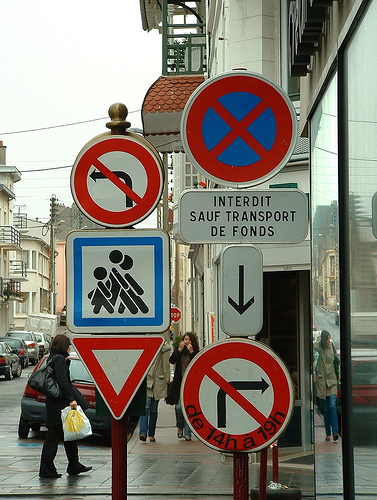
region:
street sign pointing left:
[47, 117, 168, 223]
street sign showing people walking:
[58, 223, 199, 339]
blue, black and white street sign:
[65, 228, 175, 330]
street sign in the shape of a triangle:
[68, 326, 169, 419]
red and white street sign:
[65, 332, 168, 423]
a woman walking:
[23, 334, 141, 485]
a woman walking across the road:
[14, 334, 178, 488]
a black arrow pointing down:
[213, 243, 269, 341]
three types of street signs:
[63, 126, 184, 417]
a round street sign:
[169, 63, 298, 190]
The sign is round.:
[173, 64, 300, 189]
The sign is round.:
[172, 334, 298, 454]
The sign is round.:
[67, 133, 167, 229]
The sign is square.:
[60, 225, 173, 334]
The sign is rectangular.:
[217, 243, 266, 337]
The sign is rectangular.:
[174, 187, 312, 246]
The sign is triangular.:
[67, 331, 173, 422]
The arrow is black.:
[223, 257, 258, 318]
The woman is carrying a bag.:
[20, 330, 97, 487]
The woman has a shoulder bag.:
[22, 333, 98, 488]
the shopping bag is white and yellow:
[60, 405, 97, 437]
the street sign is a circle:
[183, 349, 291, 455]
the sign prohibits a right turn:
[180, 337, 294, 454]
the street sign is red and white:
[72, 336, 167, 417]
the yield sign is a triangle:
[69, 334, 164, 420]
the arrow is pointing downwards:
[219, 245, 262, 336]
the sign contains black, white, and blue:
[68, 235, 161, 327]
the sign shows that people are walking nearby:
[72, 235, 160, 327]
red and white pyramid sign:
[69, 332, 158, 413]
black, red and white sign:
[178, 336, 290, 450]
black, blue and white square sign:
[72, 236, 159, 324]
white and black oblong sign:
[218, 242, 261, 332]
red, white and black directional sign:
[70, 130, 161, 225]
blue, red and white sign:
[178, 67, 296, 186]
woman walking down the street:
[163, 329, 196, 440]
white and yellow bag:
[59, 402, 90, 438]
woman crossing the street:
[36, 332, 88, 476]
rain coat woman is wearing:
[312, 340, 338, 395]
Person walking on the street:
[25, 333, 93, 478]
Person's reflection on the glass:
[309, 327, 341, 442]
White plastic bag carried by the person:
[58, 403, 94, 442]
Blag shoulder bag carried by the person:
[28, 354, 66, 399]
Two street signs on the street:
[66, 67, 310, 499]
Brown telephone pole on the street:
[44, 193, 58, 313]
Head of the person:
[47, 333, 72, 356]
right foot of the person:
[136, 431, 145, 441]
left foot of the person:
[147, 433, 158, 443]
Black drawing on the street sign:
[85, 248, 150, 315]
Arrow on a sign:
[223, 237, 258, 335]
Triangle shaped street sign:
[70, 334, 168, 418]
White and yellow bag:
[60, 406, 93, 442]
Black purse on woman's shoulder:
[28, 364, 66, 399]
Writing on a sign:
[180, 403, 288, 447]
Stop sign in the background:
[167, 309, 183, 322]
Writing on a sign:
[182, 190, 301, 242]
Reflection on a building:
[310, 326, 338, 443]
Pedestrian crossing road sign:
[63, 224, 169, 330]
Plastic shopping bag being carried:
[55, 400, 99, 449]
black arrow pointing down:
[223, 261, 256, 322]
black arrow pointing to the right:
[212, 375, 270, 429]